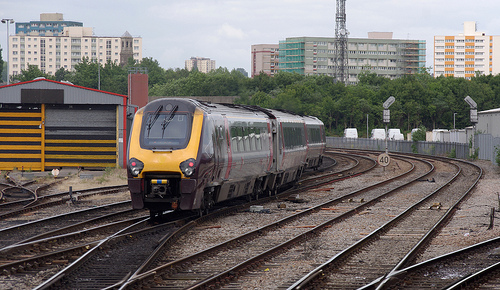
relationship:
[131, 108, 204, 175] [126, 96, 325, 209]
paint on train